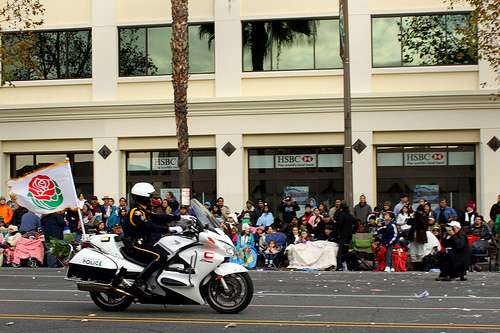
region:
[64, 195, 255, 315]
the bike is white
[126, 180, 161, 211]
the man is wearing a helmet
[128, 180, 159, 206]
the helmet is white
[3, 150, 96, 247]
the flag is white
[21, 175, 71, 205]
the flag has a rose on it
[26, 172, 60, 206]
the rose is red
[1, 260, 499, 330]
the road is dirty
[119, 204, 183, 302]
the man is wearing a black uniform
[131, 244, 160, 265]
the mans pants have a yellow stripe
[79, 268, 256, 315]
the tires are black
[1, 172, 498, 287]
the people are watching the man on the bike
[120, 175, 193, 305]
the man is wearing black clothing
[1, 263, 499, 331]
the road has litter on it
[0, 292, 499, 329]
the road has yellow stripes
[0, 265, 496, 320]
the road has white stripes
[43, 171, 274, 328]
a police motorcycle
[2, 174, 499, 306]
people are standing along the road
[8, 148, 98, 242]
the flag has a flower on it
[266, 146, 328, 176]
the sign says HSBC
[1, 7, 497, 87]
the building has windows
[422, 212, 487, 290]
a man is taking photographs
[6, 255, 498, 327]
the road is littered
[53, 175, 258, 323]
the officer is wearing a helmet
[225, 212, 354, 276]
people are covered in blankets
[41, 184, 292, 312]
the motorcycle is black and white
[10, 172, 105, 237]
a flag with a rose on it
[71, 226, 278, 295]
a white motorcycle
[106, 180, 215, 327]
a cop in dress uniform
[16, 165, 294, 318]
a police officer riding a motorcycle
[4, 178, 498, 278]
a bunch of people watching a parade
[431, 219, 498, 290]
a man taking a photo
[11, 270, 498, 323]
a road full of colorful debris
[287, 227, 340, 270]
children sitting under a white blanket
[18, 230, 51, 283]
pink blanket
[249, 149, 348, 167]
a sign that says HBC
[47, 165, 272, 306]
policeman riding a beautiful white motor cycle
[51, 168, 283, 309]
policeman wearing a safety helmet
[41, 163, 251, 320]
policeman wearing a blue uniform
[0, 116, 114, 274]
white flag with a rose picture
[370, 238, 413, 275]
young child wearing a red coat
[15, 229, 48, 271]
person wrapped in a pink blanket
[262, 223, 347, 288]
a few people wrapped in a white blanket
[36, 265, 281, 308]
motorcycle with two black tires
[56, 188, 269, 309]
motorcycle with the letter p on it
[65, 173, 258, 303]
motorcycle with the letter o on it